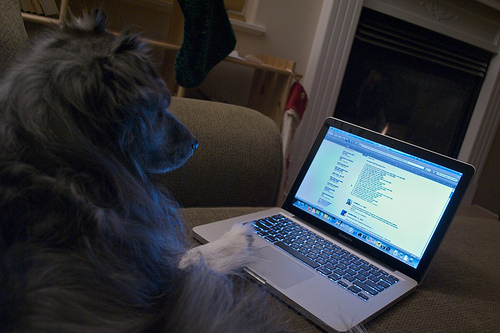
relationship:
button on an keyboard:
[316, 246, 331, 260] [243, 213, 399, 300]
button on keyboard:
[354, 280, 378, 295] [243, 213, 399, 300]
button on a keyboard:
[295, 233, 307, 242] [243, 213, 399, 300]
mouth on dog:
[151, 138, 200, 177] [0, 12, 256, 309]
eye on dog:
[149, 105, 169, 122] [0, 11, 370, 332]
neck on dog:
[8, 132, 145, 207] [0, 11, 370, 332]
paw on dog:
[175, 225, 258, 280] [0, 11, 370, 332]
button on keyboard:
[348, 281, 358, 293] [257, 219, 422, 294]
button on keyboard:
[354, 277, 383, 295] [170, 201, 417, 331]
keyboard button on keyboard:
[362, 260, 372, 273] [237, 205, 412, 316]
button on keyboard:
[348, 281, 358, 293] [243, 213, 399, 300]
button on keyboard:
[278, 218, 288, 224] [243, 213, 399, 300]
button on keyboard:
[276, 212, 287, 218] [243, 213, 399, 300]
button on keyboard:
[283, 217, 292, 224] [243, 213, 399, 300]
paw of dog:
[175, 218, 273, 280] [0, 0, 370, 330]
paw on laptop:
[175, 218, 273, 280] [183, 103, 478, 331]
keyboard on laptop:
[236, 203, 406, 305] [183, 103, 478, 331]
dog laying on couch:
[0, 11, 370, 332] [5, 0, 288, 199]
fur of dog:
[44, 123, 156, 294] [0, 11, 370, 332]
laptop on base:
[182, 123, 471, 332] [194, 194, 420, 328]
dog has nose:
[0, 0, 370, 330] [183, 131, 204, 158]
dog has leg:
[0, 11, 370, 332] [206, 224, 293, 278]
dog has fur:
[0, 11, 370, 332] [57, 194, 173, 283]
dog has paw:
[0, 11, 370, 332] [175, 225, 258, 280]